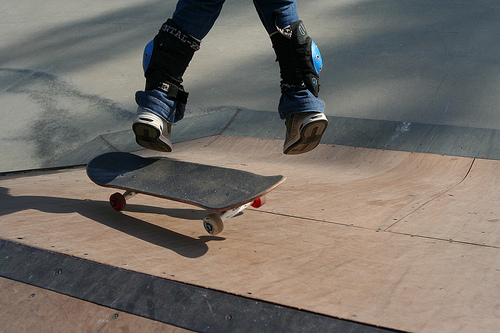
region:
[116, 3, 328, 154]
a skater is in mid air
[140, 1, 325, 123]
the skater is wearing jeans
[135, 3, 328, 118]
the jeans are blue in color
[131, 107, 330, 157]
the skater is wearing sneakers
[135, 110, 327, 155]
the soles are white in color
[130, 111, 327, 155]
the soles are made of rubber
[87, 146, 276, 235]
the skateboard is half way in the air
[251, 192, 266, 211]
the wheel is red in color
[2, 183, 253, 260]
a shadow is on the ground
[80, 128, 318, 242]
the skateboard is black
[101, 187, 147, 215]
the wheel is red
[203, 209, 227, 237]
the wheel is white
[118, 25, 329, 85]
he has shin guards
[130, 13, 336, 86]
shin guards are blue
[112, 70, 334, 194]
He is in the air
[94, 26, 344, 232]
Skate boarder is jumping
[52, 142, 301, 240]
skateboard is on the ground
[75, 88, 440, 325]
he is on a ramp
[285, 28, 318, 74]
the shin guards are black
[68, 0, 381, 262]
person skateboarding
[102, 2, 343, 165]
person in the air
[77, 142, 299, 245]
black skateboard hovering over the ramp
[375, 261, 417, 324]
black mark on the ramp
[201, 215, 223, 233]
white wheel on the skateboard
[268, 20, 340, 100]
protective pad on the leg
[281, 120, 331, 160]
bottom of the shoe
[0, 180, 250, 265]
shadow on the ground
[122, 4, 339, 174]
feet are apart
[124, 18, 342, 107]
black and blue shin guards on person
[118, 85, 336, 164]
grey and white sneakers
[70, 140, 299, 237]
short black skateboard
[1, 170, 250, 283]
black shadow of skateboarder on skate ramp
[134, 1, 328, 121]
pair of blue jeans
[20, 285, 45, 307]
nail in skate ramp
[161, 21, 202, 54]
white letters on black skate pads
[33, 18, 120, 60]
patch of cement skateboard ramp surface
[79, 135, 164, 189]
black shadow on tip of skateboard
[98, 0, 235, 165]
a leg of a person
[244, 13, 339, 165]
a leg of a person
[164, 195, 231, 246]
the wheel on a skate board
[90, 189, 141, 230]
the wheel on a skate board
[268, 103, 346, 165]
this is a shoe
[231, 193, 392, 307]
the floor is made of concrete